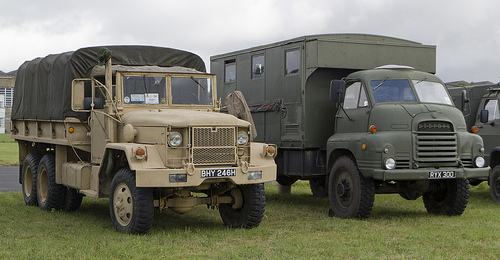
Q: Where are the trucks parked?
A: On grass.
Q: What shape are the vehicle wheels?
A: Circle.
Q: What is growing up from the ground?
A: Grass.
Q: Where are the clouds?
A: In the sky.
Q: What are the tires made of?
A: Rubber.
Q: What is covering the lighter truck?
A: Tarp.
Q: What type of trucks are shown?
A: Army trucks.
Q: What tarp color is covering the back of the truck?
A: Green.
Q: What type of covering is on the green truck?
A: Metal.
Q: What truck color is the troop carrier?
A: Tan.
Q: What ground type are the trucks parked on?
A: Grass.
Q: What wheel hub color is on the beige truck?
A: Beige.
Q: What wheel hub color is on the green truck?
A: Green.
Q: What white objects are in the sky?
A: Clouds.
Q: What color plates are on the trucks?
A: Black and white.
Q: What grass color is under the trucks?
A: Green.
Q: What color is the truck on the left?
A: Tan.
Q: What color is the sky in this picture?
A: Grey.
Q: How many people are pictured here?
A: Zero.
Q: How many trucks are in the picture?
A: Three.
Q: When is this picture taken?
A: Daytime.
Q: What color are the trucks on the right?
A: Green.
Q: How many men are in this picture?
A: Zero.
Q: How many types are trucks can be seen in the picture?
A: Three.